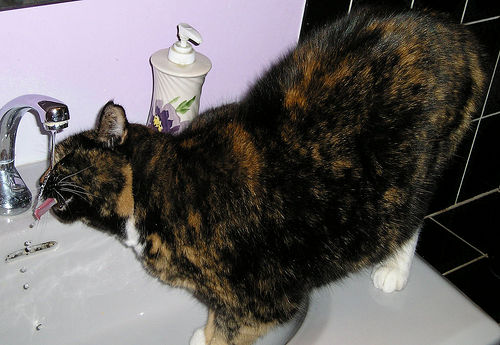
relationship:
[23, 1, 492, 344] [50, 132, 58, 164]
cat drinking water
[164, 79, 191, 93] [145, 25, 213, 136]
liquid in bottle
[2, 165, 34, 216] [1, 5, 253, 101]
steel fixed to wall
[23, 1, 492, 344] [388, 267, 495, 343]
cat standing on washbasin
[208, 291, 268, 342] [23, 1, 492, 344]
leg of cat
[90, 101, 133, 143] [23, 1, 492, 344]
ear of cat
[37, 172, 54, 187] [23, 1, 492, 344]
nose of cat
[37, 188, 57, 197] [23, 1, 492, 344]
mustache of cat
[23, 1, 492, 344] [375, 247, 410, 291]
cat has white feet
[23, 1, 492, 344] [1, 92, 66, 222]
cat drinking from a facuet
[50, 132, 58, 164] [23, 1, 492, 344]
water dripping from cat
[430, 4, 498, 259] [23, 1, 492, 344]
tiles behind cat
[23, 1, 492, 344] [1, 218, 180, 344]
cat standing on sink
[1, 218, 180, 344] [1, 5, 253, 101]
sink on wall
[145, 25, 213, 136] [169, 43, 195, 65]
container of soap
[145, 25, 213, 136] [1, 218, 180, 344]
bottle on sink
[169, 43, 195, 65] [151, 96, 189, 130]
soap with flowered design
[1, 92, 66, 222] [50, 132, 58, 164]
facuet running water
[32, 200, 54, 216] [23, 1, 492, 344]
tongue of a cat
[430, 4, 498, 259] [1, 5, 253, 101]
tiles on wall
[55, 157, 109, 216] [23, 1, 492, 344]
whiskers on a cat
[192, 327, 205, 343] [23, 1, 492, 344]
white paw on a cat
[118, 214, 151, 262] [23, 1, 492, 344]
white patch on a cat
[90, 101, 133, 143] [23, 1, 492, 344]
ear of a cat